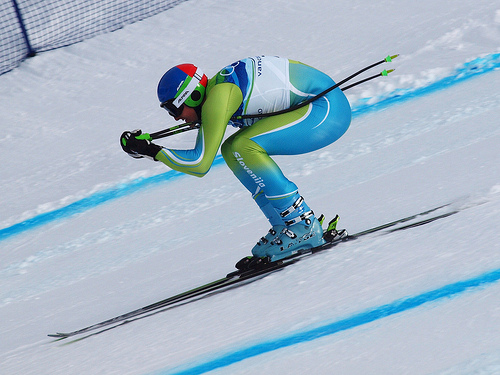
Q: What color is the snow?
A: White.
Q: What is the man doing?
A: Skiing.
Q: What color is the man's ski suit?
A: Blue and green.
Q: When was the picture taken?
A: In the winter.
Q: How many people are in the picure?
A: One.